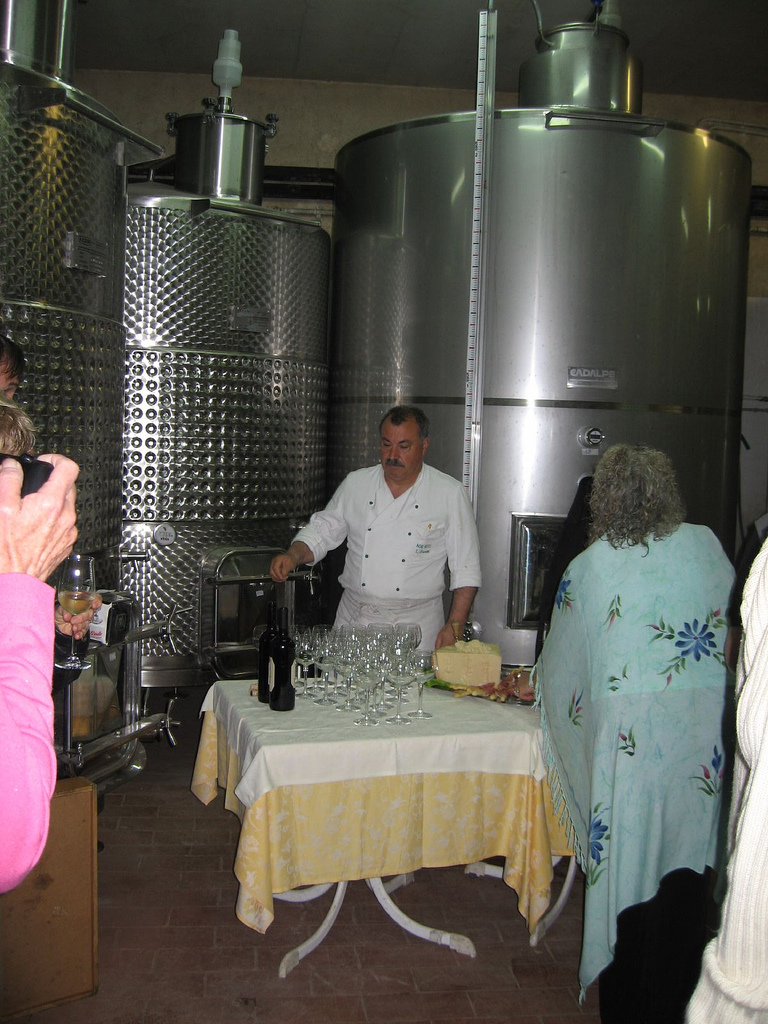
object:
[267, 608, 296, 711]
bottle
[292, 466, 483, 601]
jacket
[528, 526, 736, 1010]
blue-floral shaw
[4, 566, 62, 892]
pink sleeve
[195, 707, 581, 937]
table cloth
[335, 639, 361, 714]
vessel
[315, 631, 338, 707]
vessel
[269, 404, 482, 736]
man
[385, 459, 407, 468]
moustache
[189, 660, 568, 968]
table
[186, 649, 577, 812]
table cloth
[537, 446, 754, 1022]
woman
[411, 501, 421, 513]
buttons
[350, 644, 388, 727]
glasses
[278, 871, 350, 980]
legs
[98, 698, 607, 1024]
floor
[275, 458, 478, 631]
coat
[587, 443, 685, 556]
hair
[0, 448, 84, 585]
hand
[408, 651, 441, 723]
glasses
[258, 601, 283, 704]
bottle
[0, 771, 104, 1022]
box